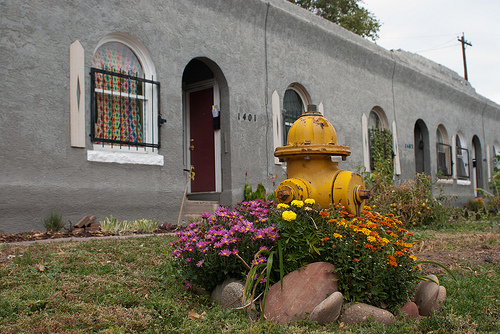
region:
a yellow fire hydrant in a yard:
[270, 101, 370, 226]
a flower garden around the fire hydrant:
[175, 185, 425, 308]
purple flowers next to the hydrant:
[173, 198, 278, 283]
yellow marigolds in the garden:
[270, 195, 315, 246]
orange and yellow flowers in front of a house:
[280, 60, 418, 295]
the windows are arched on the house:
[56, 26, 496, 214]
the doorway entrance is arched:
[177, 48, 232, 221]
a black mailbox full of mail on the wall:
[206, 102, 221, 133]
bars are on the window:
[87, 63, 162, 154]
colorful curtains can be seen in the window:
[89, 35, 148, 152]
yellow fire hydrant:
[272, 99, 366, 219]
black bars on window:
[81, 36, 171, 166]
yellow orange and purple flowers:
[176, 202, 430, 292]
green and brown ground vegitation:
[7, 245, 202, 331]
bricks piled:
[68, 215, 100, 231]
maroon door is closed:
[180, 85, 224, 197]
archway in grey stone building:
[406, 113, 441, 215]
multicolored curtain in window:
[81, 36, 157, 148]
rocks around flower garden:
[196, 258, 446, 323]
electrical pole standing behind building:
[422, 26, 482, 78]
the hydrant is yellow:
[274, 110, 413, 212]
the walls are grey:
[289, 54, 457, 108]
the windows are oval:
[365, 96, 498, 177]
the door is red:
[189, 92, 220, 202]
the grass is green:
[69, 257, 177, 331]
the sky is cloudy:
[410, 22, 499, 72]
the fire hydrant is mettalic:
[279, 103, 399, 250]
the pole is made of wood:
[433, 37, 485, 84]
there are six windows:
[70, 68, 497, 166]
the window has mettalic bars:
[87, 65, 184, 157]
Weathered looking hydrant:
[271, 109, 372, 219]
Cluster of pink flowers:
[179, 197, 271, 278]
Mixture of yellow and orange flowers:
[327, 200, 412, 297]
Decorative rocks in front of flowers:
[178, 255, 449, 325]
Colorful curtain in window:
[94, 42, 146, 72]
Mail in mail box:
[208, 104, 220, 135]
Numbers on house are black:
[229, 99, 271, 134]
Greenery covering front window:
[367, 114, 398, 174]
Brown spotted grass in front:
[2, 234, 169, 330]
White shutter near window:
[61, 35, 109, 164]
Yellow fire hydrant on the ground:
[266, 95, 378, 284]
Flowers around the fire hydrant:
[173, 185, 426, 305]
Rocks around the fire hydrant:
[216, 259, 448, 321]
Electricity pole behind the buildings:
[455, 27, 478, 84]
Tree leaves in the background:
[302, 0, 387, 45]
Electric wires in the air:
[416, 33, 468, 54]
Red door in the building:
[187, 87, 215, 193]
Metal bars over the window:
[88, 61, 168, 151]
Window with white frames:
[92, 23, 162, 163]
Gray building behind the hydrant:
[3, 2, 496, 224]